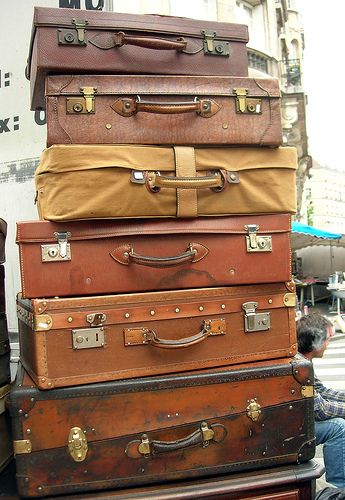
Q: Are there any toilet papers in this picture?
A: No, there are no toilet papers.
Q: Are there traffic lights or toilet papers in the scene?
A: No, there are no toilet papers or traffic lights.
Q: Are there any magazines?
A: No, there are no magazines.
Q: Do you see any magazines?
A: No, there are no magazines.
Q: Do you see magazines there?
A: No, there are no magazines.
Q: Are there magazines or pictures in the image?
A: No, there are no magazines or pictures.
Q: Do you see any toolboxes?
A: No, there are no toolboxes.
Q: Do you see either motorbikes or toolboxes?
A: No, there are no toolboxes or motorbikes.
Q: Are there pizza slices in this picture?
A: No, there are no pizza slices.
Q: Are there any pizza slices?
A: No, there are no pizza slices.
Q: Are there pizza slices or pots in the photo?
A: No, there are no pizza slices or pots.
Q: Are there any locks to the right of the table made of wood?
A: Yes, there is a lock to the right of the table.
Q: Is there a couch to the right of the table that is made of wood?
A: No, there is a lock to the right of the table.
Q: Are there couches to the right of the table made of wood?
A: No, there is a lock to the right of the table.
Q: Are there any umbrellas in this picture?
A: No, there are no umbrellas.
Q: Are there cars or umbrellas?
A: No, there are no umbrellas or cars.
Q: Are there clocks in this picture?
A: No, there are no clocks.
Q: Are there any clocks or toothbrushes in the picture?
A: No, there are no clocks or toothbrushes.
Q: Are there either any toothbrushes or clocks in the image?
A: No, there are no clocks or toothbrushes.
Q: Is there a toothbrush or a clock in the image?
A: No, there are no clocks or toothbrushes.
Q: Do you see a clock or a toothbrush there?
A: No, there are no clocks or toothbrushes.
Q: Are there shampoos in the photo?
A: No, there are no shampoos.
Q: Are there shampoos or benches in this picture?
A: No, there are no shampoos or benches.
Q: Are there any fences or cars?
A: No, there are no fences or cars.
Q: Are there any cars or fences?
A: No, there are no fences or cars.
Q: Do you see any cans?
A: No, there are no cans.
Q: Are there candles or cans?
A: No, there are no cans or candles.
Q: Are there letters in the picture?
A: Yes, there are letters.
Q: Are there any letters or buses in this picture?
A: Yes, there are letters.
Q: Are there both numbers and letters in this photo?
A: No, there are letters but no numbers.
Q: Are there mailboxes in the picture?
A: No, there are no mailboxes.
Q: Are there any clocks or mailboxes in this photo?
A: No, there are no mailboxes or clocks.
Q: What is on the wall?
A: The letters are on the wall.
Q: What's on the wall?
A: The letters are on the wall.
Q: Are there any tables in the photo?
A: Yes, there is a table.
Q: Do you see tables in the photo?
A: Yes, there is a table.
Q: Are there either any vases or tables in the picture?
A: Yes, there is a table.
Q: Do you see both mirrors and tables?
A: No, there is a table but no mirrors.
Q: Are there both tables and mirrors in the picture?
A: No, there is a table but no mirrors.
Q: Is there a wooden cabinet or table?
A: Yes, there is a wood table.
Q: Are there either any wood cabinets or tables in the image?
A: Yes, there is a wood table.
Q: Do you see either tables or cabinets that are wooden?
A: Yes, the table is wooden.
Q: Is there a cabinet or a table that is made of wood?
A: Yes, the table is made of wood.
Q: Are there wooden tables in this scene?
A: Yes, there is a wood table.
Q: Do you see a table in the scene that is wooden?
A: Yes, there is a table that is wooden.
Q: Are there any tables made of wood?
A: Yes, there is a table that is made of wood.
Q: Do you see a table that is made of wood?
A: Yes, there is a table that is made of wood.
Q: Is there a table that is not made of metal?
A: Yes, there is a table that is made of wood.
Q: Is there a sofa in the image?
A: No, there are no sofas.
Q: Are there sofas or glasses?
A: No, there are no sofas or glasses.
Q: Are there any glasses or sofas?
A: No, there are no sofas or glasses.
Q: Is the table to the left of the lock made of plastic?
A: No, the table is made of wood.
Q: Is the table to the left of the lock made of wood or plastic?
A: The table is made of wood.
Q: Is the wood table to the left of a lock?
A: Yes, the table is to the left of a lock.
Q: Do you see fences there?
A: No, there are no fences.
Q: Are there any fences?
A: No, there are no fences.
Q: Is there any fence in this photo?
A: No, there are no fences.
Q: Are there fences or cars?
A: No, there are no fences or cars.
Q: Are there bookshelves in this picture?
A: No, there are no bookshelves.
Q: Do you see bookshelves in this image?
A: No, there are no bookshelves.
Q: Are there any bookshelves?
A: No, there are no bookshelves.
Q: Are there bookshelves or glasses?
A: No, there are no bookshelves or glasses.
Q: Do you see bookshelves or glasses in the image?
A: No, there are no bookshelves or glasses.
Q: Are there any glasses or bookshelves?
A: No, there are no bookshelves or glasses.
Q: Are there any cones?
A: No, there are no cones.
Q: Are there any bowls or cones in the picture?
A: No, there are no cones or bowls.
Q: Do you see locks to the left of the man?
A: Yes, there is a lock to the left of the man.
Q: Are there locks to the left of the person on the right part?
A: Yes, there is a lock to the left of the man.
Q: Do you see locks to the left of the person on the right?
A: Yes, there is a lock to the left of the man.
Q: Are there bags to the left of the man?
A: No, there is a lock to the left of the man.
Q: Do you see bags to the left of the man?
A: No, there is a lock to the left of the man.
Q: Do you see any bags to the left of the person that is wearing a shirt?
A: No, there is a lock to the left of the man.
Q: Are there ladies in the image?
A: No, there are no ladies.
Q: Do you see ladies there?
A: No, there are no ladies.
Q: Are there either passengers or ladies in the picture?
A: No, there are no ladies or passengers.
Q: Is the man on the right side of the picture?
A: Yes, the man is on the right of the image.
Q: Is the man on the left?
A: No, the man is on the right of the image.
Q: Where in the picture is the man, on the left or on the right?
A: The man is on the right of the image.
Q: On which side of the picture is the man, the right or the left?
A: The man is on the right of the image.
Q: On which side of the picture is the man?
A: The man is on the right of the image.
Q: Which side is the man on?
A: The man is on the right of the image.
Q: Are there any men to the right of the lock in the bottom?
A: Yes, there is a man to the right of the lock.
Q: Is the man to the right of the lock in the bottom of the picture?
A: Yes, the man is to the right of the lock.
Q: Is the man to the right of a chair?
A: No, the man is to the right of the lock.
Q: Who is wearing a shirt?
A: The man is wearing a shirt.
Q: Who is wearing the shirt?
A: The man is wearing a shirt.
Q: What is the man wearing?
A: The man is wearing a shirt.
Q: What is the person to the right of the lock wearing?
A: The man is wearing a shirt.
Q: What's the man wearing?
A: The man is wearing a shirt.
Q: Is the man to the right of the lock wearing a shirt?
A: Yes, the man is wearing a shirt.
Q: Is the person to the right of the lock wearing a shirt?
A: Yes, the man is wearing a shirt.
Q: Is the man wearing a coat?
A: No, the man is wearing a shirt.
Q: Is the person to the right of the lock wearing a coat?
A: No, the man is wearing a shirt.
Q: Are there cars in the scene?
A: No, there are no cars.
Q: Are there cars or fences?
A: No, there are no cars or fences.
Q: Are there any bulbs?
A: No, there are no bulbs.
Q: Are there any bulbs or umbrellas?
A: No, there are no bulbs or umbrellas.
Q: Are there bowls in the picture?
A: No, there are no bowls.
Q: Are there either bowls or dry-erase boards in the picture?
A: No, there are no bowls or dry-erase boards.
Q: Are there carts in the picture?
A: No, there are no carts.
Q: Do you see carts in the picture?
A: No, there are no carts.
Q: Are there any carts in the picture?
A: No, there are no carts.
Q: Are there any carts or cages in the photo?
A: No, there are no carts or cages.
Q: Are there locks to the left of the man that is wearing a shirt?
A: Yes, there is a lock to the left of the man.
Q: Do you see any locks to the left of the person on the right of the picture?
A: Yes, there is a lock to the left of the man.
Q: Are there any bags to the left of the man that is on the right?
A: No, there is a lock to the left of the man.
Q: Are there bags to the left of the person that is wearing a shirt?
A: No, there is a lock to the left of the man.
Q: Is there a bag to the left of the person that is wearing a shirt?
A: No, there is a lock to the left of the man.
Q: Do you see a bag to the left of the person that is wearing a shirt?
A: No, there is a lock to the left of the man.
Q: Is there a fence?
A: No, there are no fences.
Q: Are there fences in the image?
A: No, there are no fences.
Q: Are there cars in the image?
A: No, there are no cars.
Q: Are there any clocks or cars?
A: No, there are no cars or clocks.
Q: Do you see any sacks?
A: No, there are no sacks.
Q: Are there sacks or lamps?
A: No, there are no sacks or lamps.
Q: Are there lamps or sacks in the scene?
A: No, there are no sacks or lamps.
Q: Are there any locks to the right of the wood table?
A: Yes, there is a lock to the right of the table.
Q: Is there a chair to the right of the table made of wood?
A: No, there is a lock to the right of the table.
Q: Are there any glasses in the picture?
A: No, there are no glasses.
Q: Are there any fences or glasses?
A: No, there are no glasses or fences.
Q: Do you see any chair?
A: No, there are no chairs.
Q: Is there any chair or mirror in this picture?
A: No, there are no chairs or mirrors.